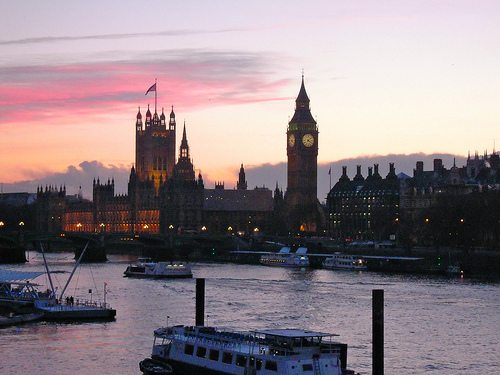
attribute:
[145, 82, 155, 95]
flag — blowing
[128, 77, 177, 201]
building — lit, castle, large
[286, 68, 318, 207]
tower — large, stone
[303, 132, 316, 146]
clock — lit, landmark, large, round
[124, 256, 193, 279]
boat — white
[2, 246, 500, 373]
river — calm, rippled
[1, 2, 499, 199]
sky — red, orange, clear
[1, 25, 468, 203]
clouds — pink, blue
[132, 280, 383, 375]
boat — large, white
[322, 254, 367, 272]
boat — white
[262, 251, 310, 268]
boat — white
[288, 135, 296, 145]
clock — large, lit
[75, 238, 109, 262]
support — stone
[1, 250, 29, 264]
support — stone